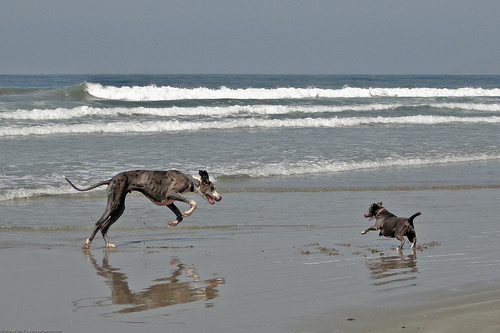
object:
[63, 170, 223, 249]
dog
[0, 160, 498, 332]
beach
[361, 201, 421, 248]
dog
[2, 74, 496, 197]
ocean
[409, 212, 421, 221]
tail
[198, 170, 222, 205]
head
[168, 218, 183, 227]
front foot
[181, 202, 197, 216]
front foot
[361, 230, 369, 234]
front foot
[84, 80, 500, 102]
wave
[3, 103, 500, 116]
wave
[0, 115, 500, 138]
wave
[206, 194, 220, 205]
mouth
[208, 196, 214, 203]
inside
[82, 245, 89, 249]
rear paw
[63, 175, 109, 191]
tail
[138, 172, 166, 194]
ribs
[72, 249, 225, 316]
shadow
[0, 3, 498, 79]
sky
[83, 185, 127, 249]
leg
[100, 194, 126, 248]
leg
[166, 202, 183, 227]
leg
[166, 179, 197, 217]
leg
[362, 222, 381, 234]
leg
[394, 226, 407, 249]
leg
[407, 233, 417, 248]
leg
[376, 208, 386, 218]
collar